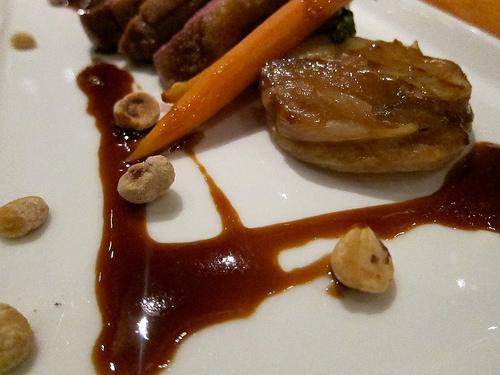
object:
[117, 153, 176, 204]
peanut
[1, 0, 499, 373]
plate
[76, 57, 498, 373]
sauce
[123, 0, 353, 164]
carrot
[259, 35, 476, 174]
pastry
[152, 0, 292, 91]
meat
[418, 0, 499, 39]
table